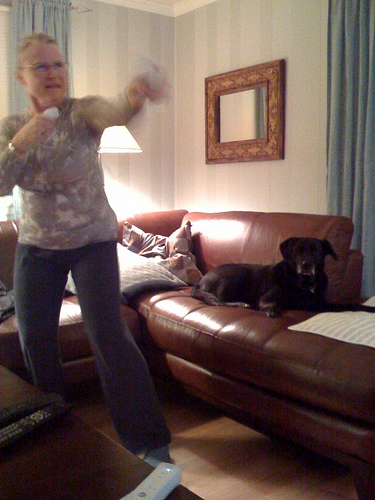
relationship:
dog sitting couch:
[187, 235, 324, 312] [114, 198, 362, 444]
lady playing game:
[0, 30, 174, 468] [35, 59, 165, 142]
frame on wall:
[203, 57, 286, 165] [190, 33, 278, 52]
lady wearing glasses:
[0, 30, 174, 468] [24, 53, 72, 74]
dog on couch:
[193, 233, 334, 323] [114, 198, 362, 444]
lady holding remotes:
[0, 30, 174, 468] [18, 63, 161, 124]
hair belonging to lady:
[12, 29, 59, 72] [0, 30, 174, 468]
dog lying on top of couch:
[193, 233, 334, 323] [1, 207, 363, 498]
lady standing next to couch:
[0, 30, 174, 468] [1, 207, 363, 498]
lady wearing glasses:
[0, 30, 174, 468] [17, 58, 69, 72]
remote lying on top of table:
[1, 398, 74, 451] [1, 366, 204, 498]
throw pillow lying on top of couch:
[64, 242, 188, 306] [1, 207, 363, 498]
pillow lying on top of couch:
[115, 217, 209, 286] [1, 207, 363, 498]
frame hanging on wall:
[203, 57, 286, 165] [175, 1, 327, 215]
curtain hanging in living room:
[323, 0, 363, 297] [1, 1, 363, 497]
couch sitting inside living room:
[1, 207, 363, 498] [1, 1, 363, 497]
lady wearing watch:
[0, 30, 174, 468] [6, 139, 27, 156]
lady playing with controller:
[0, 30, 174, 468] [132, 53, 174, 104]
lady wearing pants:
[0, 30, 174, 468] [12, 238, 172, 453]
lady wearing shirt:
[0, 30, 174, 468] [0, 96, 143, 250]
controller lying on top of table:
[110, 458, 191, 498] [1, 366, 204, 498]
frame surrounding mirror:
[203, 57, 286, 165] [217, 85, 268, 142]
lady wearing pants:
[0, 30, 174, 468] [16, 237, 183, 457]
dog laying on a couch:
[193, 233, 334, 323] [116, 201, 373, 471]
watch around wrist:
[6, 139, 28, 160] [6, 127, 30, 163]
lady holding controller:
[0, 30, 174, 468] [132, 53, 174, 104]